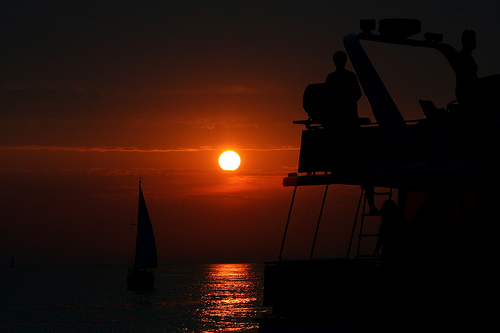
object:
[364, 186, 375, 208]
leg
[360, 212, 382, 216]
rung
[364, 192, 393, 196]
rung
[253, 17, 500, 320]
boat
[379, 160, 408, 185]
ground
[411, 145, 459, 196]
ground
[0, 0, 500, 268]
sky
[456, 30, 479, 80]
person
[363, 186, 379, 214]
silhouette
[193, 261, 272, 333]
reflection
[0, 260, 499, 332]
water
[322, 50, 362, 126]
figure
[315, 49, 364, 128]
people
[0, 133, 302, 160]
line sky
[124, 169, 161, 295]
boat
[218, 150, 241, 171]
bright sun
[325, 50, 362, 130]
silhouette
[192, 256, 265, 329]
seawater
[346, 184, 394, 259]
ladder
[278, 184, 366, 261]
slanted supports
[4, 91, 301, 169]
cloud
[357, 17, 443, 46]
lights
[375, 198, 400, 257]
person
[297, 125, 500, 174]
platform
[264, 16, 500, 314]
back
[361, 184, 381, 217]
man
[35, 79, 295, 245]
sunset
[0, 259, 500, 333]
lake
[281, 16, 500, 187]
open structure